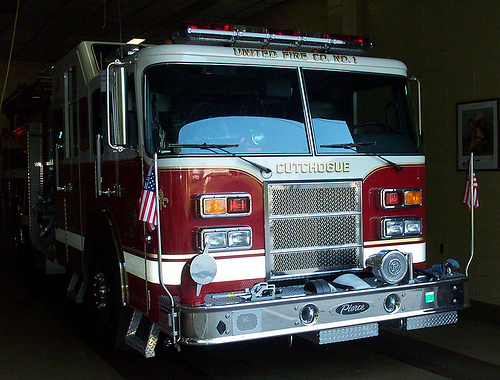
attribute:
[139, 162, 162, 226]
flag — small, american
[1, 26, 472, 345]
truck — bright red, red, clean, ready, shiny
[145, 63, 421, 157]
window — reflective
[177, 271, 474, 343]
bumper — silver, metallic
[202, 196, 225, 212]
signal light — yellow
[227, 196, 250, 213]
light — red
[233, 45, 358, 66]
name — gold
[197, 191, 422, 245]
headlights — red, orange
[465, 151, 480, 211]
flag — american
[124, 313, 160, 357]
step — silver, metal